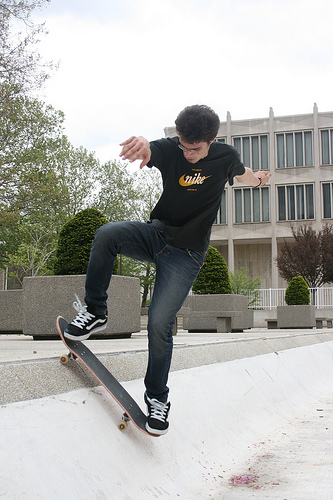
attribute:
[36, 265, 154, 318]
block — concrete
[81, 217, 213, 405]
jeans — blue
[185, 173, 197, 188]
letter — white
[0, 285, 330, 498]
concrete — plant holders, square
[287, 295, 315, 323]
planter — large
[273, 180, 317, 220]
windows — long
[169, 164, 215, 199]
letter — white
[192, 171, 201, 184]
k — white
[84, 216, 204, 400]
dark jeans — skinny, faded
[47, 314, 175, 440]
skateboard — black, white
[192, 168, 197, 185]
letter i — white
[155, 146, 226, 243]
shirt — black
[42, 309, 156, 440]
scateboard — black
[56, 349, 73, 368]
wheel — small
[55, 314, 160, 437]
skateboard — black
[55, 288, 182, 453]
skateboard — black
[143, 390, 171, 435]
shoe — black, white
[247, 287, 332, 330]
fence — white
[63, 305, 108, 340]
shoe — white, black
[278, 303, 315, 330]
block — concrete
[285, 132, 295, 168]
windows — long